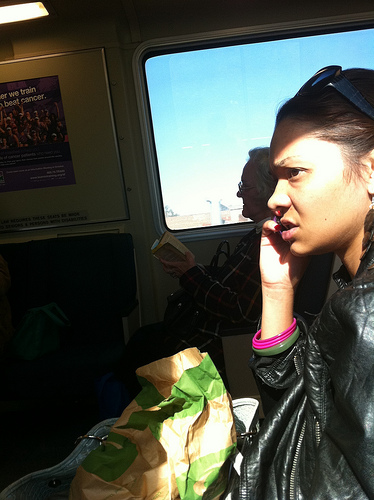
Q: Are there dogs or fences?
A: No, there are no fences or dogs.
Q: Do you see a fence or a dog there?
A: No, there are no fences or dogs.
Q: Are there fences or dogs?
A: No, there are no fences or dogs.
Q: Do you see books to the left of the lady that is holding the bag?
A: Yes, there is a book to the left of the lady.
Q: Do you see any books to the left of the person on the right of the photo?
A: Yes, there is a book to the left of the lady.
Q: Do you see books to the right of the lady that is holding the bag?
A: No, the book is to the left of the lady.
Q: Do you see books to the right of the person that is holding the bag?
A: No, the book is to the left of the lady.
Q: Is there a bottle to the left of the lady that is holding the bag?
A: No, there is a book to the left of the lady.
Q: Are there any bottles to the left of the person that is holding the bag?
A: No, there is a book to the left of the lady.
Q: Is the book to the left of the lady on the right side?
A: Yes, the book is to the left of the lady.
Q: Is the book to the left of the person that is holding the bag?
A: Yes, the book is to the left of the lady.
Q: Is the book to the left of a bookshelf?
A: No, the book is to the left of the lady.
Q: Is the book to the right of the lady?
A: No, the book is to the left of the lady.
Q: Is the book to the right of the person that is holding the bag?
A: No, the book is to the left of the lady.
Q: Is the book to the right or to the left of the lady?
A: The book is to the left of the lady.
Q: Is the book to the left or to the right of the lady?
A: The book is to the left of the lady.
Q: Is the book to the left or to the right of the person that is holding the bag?
A: The book is to the left of the lady.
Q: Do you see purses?
A: Yes, there is a purse.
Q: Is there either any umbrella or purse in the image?
A: Yes, there is a purse.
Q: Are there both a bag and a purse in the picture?
A: Yes, there are both a purse and a bag.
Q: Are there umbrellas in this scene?
A: No, there are no umbrellas.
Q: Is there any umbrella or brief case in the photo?
A: No, there are no umbrellas or briefcases.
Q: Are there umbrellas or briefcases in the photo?
A: No, there are no umbrellas or briefcases.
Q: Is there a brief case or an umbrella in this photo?
A: No, there are no umbrellas or briefcases.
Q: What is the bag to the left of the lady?
A: The bag is a purse.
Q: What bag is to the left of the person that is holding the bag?
A: The bag is a purse.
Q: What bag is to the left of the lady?
A: The bag is a purse.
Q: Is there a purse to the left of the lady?
A: Yes, there is a purse to the left of the lady.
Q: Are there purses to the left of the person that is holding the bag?
A: Yes, there is a purse to the left of the lady.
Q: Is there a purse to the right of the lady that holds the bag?
A: No, the purse is to the left of the lady.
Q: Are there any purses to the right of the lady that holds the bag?
A: No, the purse is to the left of the lady.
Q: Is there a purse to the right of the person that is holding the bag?
A: No, the purse is to the left of the lady.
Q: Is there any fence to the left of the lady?
A: No, there is a purse to the left of the lady.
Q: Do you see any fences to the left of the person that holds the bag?
A: No, there is a purse to the left of the lady.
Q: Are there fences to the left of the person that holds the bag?
A: No, there is a purse to the left of the lady.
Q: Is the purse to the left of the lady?
A: Yes, the purse is to the left of the lady.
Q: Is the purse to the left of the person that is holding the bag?
A: Yes, the purse is to the left of the lady.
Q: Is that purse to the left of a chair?
A: No, the purse is to the left of the lady.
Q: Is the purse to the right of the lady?
A: No, the purse is to the left of the lady.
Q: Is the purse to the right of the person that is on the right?
A: No, the purse is to the left of the lady.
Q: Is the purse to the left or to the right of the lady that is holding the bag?
A: The purse is to the left of the lady.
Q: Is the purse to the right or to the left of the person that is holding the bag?
A: The purse is to the left of the lady.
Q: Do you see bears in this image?
A: No, there are no bears.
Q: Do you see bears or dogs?
A: No, there are no bears or dogs.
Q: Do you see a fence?
A: No, there are no fences.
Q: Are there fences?
A: No, there are no fences.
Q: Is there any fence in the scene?
A: No, there are no fences.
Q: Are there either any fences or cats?
A: No, there are no fences or cats.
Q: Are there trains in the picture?
A: Yes, there is a train.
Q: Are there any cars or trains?
A: Yes, there is a train.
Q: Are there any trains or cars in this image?
A: Yes, there is a train.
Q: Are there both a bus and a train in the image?
A: No, there is a train but no buses.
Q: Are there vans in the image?
A: No, there are no vans.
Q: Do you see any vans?
A: No, there are no vans.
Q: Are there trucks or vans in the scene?
A: No, there are no vans or trucks.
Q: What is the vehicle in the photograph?
A: The vehicle is a train.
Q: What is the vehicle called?
A: The vehicle is a train.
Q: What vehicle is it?
A: The vehicle is a train.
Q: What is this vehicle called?
A: This is a train.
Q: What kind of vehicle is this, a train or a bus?
A: This is a train.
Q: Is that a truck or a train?
A: That is a train.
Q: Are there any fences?
A: No, there are no fences.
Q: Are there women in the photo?
A: Yes, there is a woman.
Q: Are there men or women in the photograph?
A: Yes, there is a woman.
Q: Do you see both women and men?
A: Yes, there are both a woman and a man.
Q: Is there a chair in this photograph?
A: No, there are no chairs.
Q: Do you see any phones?
A: Yes, there is a phone.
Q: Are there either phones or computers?
A: Yes, there is a phone.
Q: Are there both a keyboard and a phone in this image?
A: No, there is a phone but no keyboards.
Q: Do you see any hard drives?
A: No, there are no hard drives.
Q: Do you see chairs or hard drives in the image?
A: No, there are no hard drives or chairs.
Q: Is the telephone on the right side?
A: Yes, the telephone is on the right of the image.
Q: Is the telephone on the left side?
A: No, the telephone is on the right of the image.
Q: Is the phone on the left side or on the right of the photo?
A: The phone is on the right of the image.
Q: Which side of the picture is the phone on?
A: The phone is on the right of the image.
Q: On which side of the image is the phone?
A: The phone is on the right of the image.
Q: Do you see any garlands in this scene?
A: No, there are no garlands.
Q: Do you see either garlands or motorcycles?
A: No, there are no garlands or motorcycles.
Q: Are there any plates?
A: No, there are no plates.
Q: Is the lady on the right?
A: Yes, the lady is on the right of the image.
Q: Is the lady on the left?
A: No, the lady is on the right of the image.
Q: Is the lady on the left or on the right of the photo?
A: The lady is on the right of the image.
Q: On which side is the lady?
A: The lady is on the right of the image.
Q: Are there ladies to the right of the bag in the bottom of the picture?
A: Yes, there is a lady to the right of the bag.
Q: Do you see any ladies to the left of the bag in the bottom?
A: No, the lady is to the right of the bag.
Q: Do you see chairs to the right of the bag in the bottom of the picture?
A: No, there is a lady to the right of the bag.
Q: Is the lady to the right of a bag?
A: Yes, the lady is to the right of a bag.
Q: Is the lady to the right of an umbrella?
A: No, the lady is to the right of a bag.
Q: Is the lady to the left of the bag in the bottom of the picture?
A: No, the lady is to the right of the bag.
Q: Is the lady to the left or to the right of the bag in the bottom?
A: The lady is to the right of the bag.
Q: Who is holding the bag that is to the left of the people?
A: The lady is holding the bag.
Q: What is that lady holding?
A: The lady is holding the bag.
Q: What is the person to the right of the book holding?
A: The lady is holding the bag.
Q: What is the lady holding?
A: The lady is holding the bag.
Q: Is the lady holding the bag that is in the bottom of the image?
A: Yes, the lady is holding the bag.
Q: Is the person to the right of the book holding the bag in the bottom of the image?
A: Yes, the lady is holding the bag.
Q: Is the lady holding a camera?
A: No, the lady is holding the bag.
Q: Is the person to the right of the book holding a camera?
A: No, the lady is holding the bag.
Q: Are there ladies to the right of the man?
A: Yes, there is a lady to the right of the man.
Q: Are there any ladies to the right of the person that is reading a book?
A: Yes, there is a lady to the right of the man.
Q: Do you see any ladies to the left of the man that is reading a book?
A: No, the lady is to the right of the man.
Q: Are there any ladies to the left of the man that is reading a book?
A: No, the lady is to the right of the man.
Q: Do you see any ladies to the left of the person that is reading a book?
A: No, the lady is to the right of the man.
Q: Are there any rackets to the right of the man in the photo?
A: No, there is a lady to the right of the man.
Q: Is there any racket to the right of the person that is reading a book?
A: No, there is a lady to the right of the man.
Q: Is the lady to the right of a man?
A: Yes, the lady is to the right of a man.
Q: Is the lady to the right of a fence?
A: No, the lady is to the right of a man.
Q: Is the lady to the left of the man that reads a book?
A: No, the lady is to the right of the man.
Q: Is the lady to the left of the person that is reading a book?
A: No, the lady is to the right of the man.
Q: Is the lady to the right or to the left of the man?
A: The lady is to the right of the man.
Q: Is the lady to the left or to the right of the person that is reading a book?
A: The lady is to the right of the man.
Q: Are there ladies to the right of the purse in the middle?
A: Yes, there is a lady to the right of the purse.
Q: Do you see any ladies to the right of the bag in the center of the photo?
A: Yes, there is a lady to the right of the purse.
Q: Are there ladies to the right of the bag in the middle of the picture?
A: Yes, there is a lady to the right of the purse.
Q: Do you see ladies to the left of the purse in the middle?
A: No, the lady is to the right of the purse.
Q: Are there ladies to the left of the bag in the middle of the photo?
A: No, the lady is to the right of the purse.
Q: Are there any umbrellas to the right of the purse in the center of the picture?
A: No, there is a lady to the right of the purse.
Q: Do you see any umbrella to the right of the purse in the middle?
A: No, there is a lady to the right of the purse.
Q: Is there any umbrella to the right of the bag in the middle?
A: No, there is a lady to the right of the purse.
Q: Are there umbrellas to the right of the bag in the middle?
A: No, there is a lady to the right of the purse.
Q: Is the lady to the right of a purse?
A: Yes, the lady is to the right of a purse.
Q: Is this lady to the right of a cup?
A: No, the lady is to the right of a purse.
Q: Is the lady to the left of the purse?
A: No, the lady is to the right of the purse.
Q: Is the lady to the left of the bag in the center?
A: No, the lady is to the right of the purse.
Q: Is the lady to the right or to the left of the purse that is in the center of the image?
A: The lady is to the right of the purse.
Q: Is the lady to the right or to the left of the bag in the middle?
A: The lady is to the right of the purse.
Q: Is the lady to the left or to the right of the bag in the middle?
A: The lady is to the right of the purse.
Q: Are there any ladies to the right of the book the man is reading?
A: Yes, there is a lady to the right of the book.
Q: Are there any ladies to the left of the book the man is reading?
A: No, the lady is to the right of the book.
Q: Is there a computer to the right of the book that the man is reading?
A: No, there is a lady to the right of the book.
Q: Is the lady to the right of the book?
A: Yes, the lady is to the right of the book.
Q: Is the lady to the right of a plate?
A: No, the lady is to the right of the book.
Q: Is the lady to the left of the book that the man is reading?
A: No, the lady is to the right of the book.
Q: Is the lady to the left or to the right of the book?
A: The lady is to the right of the book.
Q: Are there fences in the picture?
A: No, there are no fences.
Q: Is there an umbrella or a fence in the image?
A: No, there are no fences or umbrellas.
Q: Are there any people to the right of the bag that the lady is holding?
A: Yes, there are people to the right of the bag.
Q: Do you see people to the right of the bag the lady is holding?
A: Yes, there are people to the right of the bag.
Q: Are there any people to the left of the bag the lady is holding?
A: No, the people are to the right of the bag.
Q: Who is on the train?
A: The people are on the train.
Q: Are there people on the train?
A: Yes, there are people on the train.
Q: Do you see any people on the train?
A: Yes, there are people on the train.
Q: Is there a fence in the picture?
A: No, there are no fences.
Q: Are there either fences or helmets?
A: No, there are no fences or helmets.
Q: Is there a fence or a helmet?
A: No, there are no fences or helmets.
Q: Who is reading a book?
A: The man is reading a book.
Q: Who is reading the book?
A: The man is reading a book.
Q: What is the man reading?
A: The man is reading a book.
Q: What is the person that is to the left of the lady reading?
A: The man is reading a book.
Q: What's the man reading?
A: The man is reading a book.